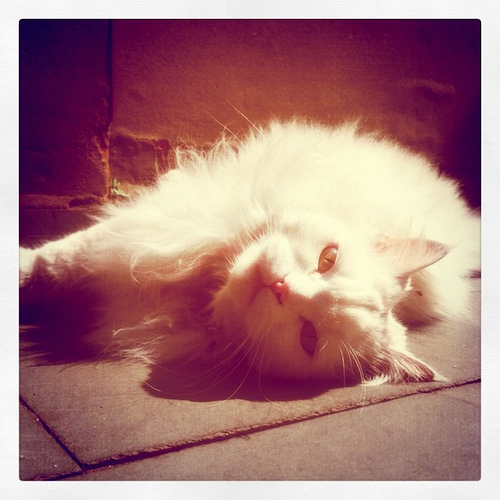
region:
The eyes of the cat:
[301, 247, 338, 356]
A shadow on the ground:
[147, 350, 328, 402]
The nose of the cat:
[273, 273, 288, 300]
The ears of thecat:
[378, 236, 449, 389]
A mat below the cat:
[17, 272, 485, 469]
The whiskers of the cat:
[133, 304, 279, 406]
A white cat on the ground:
[16, 120, 481, 383]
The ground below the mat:
[6, 380, 480, 483]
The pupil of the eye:
[321, 255, 334, 267]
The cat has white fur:
[1, 120, 478, 417]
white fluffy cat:
[38, 70, 477, 423]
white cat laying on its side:
[4, 107, 491, 395]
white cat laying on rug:
[1, 53, 426, 397]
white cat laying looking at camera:
[45, 113, 466, 385]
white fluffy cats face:
[191, 205, 474, 406]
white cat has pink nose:
[271, 276, 293, 304]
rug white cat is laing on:
[0, 269, 483, 465]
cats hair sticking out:
[67, 64, 405, 173]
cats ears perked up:
[376, 233, 441, 422]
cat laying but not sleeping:
[82, 106, 499, 409]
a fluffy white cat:
[34, 64, 438, 375]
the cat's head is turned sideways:
[204, 209, 462, 396]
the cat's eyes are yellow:
[242, 225, 369, 367]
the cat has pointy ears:
[349, 203, 492, 392]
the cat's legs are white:
[27, 168, 223, 370]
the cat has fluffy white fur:
[189, 118, 444, 214]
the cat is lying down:
[53, 147, 466, 374]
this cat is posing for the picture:
[76, 145, 441, 388]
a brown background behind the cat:
[72, 42, 476, 159]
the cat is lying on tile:
[42, 362, 426, 487]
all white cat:
[32, 99, 479, 384]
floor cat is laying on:
[18, 227, 485, 481]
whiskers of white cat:
[200, 212, 297, 385]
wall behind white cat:
[38, 29, 477, 174]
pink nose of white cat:
[268, 279, 290, 303]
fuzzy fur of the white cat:
[85, 104, 456, 276]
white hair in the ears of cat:
[372, 214, 431, 389]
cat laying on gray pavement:
[37, 89, 481, 476]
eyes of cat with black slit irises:
[294, 244, 342, 354]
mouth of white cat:
[243, 261, 265, 306]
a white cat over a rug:
[18, 97, 488, 468]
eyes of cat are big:
[290, 237, 338, 367]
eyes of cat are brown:
[290, 236, 340, 356]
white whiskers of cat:
[215, 195, 285, 390]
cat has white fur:
[13, 103, 482, 390]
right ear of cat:
[371, 329, 441, 395]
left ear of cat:
[388, 221, 456, 277]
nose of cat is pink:
[272, 274, 294, 303]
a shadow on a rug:
[128, 342, 272, 444]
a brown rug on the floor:
[29, 329, 299, 464]